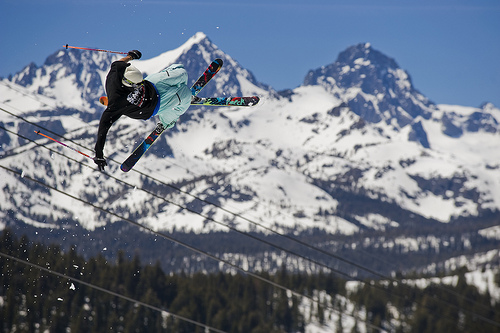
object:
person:
[89, 47, 198, 169]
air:
[0, 0, 500, 327]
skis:
[116, 58, 266, 173]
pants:
[146, 64, 197, 129]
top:
[55, 27, 399, 67]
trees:
[0, 217, 499, 328]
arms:
[93, 107, 118, 179]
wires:
[5, 143, 499, 333]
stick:
[97, 96, 110, 107]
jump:
[85, 50, 193, 172]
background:
[0, 190, 500, 259]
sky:
[0, 0, 496, 114]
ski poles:
[31, 122, 101, 160]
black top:
[90, 58, 158, 155]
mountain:
[0, 31, 500, 262]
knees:
[176, 67, 194, 86]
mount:
[298, 35, 451, 138]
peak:
[326, 33, 400, 69]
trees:
[2, 159, 497, 273]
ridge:
[89, 162, 413, 255]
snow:
[0, 30, 500, 333]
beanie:
[119, 66, 143, 90]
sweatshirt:
[92, 49, 161, 158]